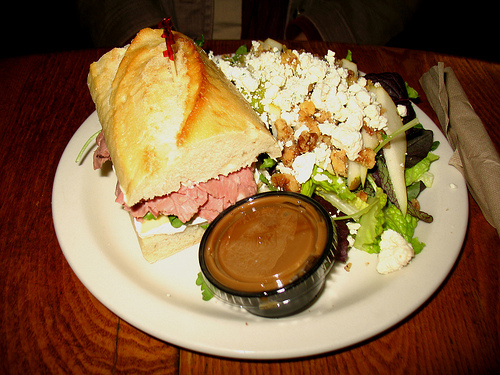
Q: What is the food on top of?
A: A plate.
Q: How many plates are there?
A: 1.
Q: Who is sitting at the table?
A: No one is pictured.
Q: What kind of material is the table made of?
A: Wood.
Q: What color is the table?
A: Brown.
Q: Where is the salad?
A: On the plate by the sandwich.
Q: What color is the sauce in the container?
A: Brownish.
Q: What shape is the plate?
A: Round.